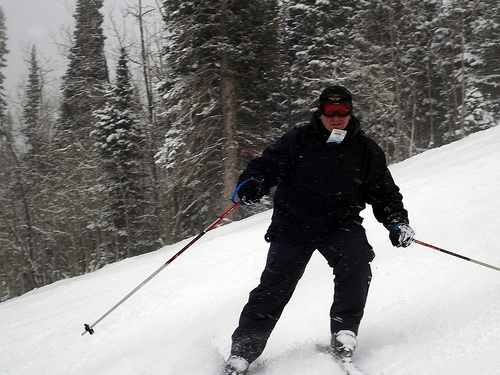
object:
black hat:
[316, 85, 349, 109]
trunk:
[217, 60, 241, 227]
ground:
[0, 123, 499, 373]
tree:
[260, 0, 420, 174]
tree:
[390, 1, 499, 161]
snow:
[0, 123, 499, 374]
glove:
[387, 216, 417, 249]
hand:
[387, 216, 415, 248]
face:
[320, 103, 351, 133]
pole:
[75, 200, 246, 338]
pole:
[410, 236, 500, 274]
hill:
[0, 122, 499, 374]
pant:
[226, 219, 374, 362]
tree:
[103, 1, 178, 218]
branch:
[134, 0, 156, 127]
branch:
[104, 11, 124, 50]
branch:
[140, 8, 153, 14]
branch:
[121, 7, 138, 19]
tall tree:
[78, 43, 160, 274]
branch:
[177, 182, 217, 217]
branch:
[188, 112, 223, 124]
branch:
[173, 141, 223, 167]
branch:
[179, 62, 215, 80]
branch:
[240, 103, 261, 118]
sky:
[0, 0, 180, 161]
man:
[223, 85, 413, 375]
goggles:
[317, 97, 350, 117]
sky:
[15, 12, 80, 82]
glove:
[238, 180, 274, 208]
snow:
[331, 325, 359, 350]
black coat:
[235, 111, 410, 246]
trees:
[0, 115, 111, 304]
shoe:
[330, 330, 361, 354]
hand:
[232, 176, 272, 207]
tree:
[81, 179, 128, 274]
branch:
[104, 208, 122, 223]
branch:
[91, 197, 106, 226]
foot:
[331, 328, 357, 360]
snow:
[151, 115, 196, 171]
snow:
[150, 75, 182, 94]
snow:
[194, 97, 216, 119]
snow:
[87, 82, 155, 155]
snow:
[412, 0, 499, 136]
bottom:
[78, 320, 94, 338]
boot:
[223, 354, 253, 374]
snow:
[222, 355, 251, 372]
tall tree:
[52, 0, 117, 170]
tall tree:
[150, 0, 288, 230]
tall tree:
[17, 43, 54, 168]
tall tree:
[0, 4, 10, 304]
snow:
[20, 85, 41, 124]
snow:
[156, 0, 254, 73]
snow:
[83, 204, 128, 274]